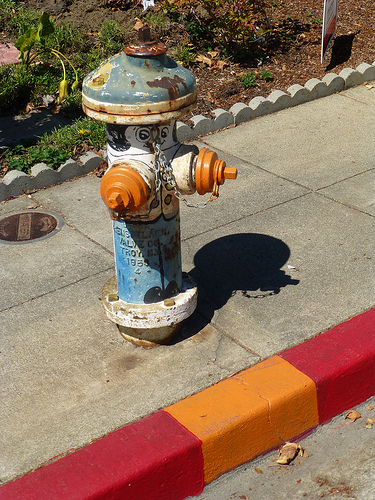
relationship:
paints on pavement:
[111, 395, 266, 488] [59, 293, 287, 411]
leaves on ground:
[343, 406, 362, 420] [78, 17, 239, 326]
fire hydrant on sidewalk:
[81, 34, 234, 346] [241, 123, 361, 351]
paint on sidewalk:
[308, 347, 339, 370] [0, 307, 373, 498]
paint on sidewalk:
[222, 389, 241, 405] [0, 307, 373, 498]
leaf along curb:
[273, 439, 309, 467] [3, 307, 373, 497]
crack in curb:
[232, 371, 277, 434] [3, 307, 373, 497]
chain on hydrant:
[161, 167, 185, 205] [61, 24, 252, 353]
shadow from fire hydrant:
[168, 222, 299, 348] [76, 21, 240, 350]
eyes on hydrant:
[139, 122, 178, 144] [62, 24, 227, 294]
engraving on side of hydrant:
[113, 226, 178, 278] [71, 13, 251, 362]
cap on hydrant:
[81, 49, 196, 104] [75, 22, 238, 349]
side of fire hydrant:
[93, 158, 158, 223] [81, 16, 239, 348]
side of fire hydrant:
[186, 139, 243, 198] [81, 16, 239, 348]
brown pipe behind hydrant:
[1, 209, 58, 241] [75, 22, 238, 349]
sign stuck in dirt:
[320, 0, 337, 63] [33, 0, 373, 120]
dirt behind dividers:
[198, 8, 312, 78] [171, 63, 374, 139]